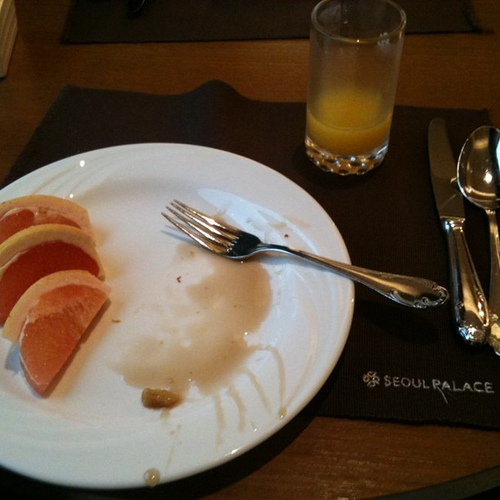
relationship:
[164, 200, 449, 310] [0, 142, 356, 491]
fork on plate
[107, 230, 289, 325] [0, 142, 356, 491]
crumbs on plate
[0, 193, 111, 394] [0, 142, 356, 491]
grapefruit on plate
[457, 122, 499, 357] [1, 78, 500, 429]
spoon on placemat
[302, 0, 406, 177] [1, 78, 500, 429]
glass on placemat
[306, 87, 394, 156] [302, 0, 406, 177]
orange juice in glass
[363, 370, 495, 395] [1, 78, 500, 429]
insignia on placemat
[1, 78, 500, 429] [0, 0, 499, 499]
placemat on table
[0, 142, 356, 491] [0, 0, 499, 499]
plate on table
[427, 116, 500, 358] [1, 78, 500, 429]
silverware on placemat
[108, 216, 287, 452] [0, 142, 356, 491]
syrup on plate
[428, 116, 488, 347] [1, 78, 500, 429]
knife on placemat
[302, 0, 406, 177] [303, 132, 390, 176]
glass has bottom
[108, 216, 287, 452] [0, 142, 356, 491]
syrup dripping off plate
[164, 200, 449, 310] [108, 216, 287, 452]
fork in syrup